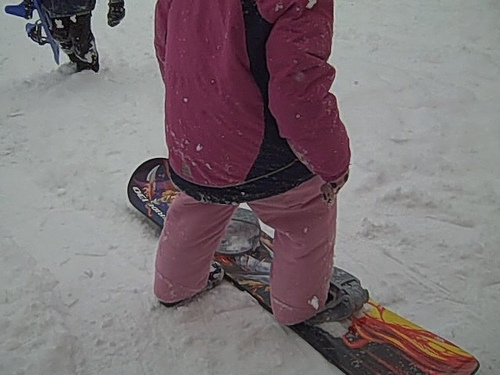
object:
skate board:
[126, 157, 480, 375]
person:
[1, 0, 126, 73]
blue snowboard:
[4, 0, 60, 65]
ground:
[418, 91, 450, 121]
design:
[339, 300, 473, 372]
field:
[21, 8, 447, 282]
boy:
[153, 0, 351, 326]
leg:
[245, 176, 341, 327]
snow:
[1, 325, 498, 372]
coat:
[153, 0, 352, 205]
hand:
[320, 171, 350, 205]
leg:
[101, 0, 126, 23]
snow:
[70, 44, 96, 65]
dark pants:
[43, 7, 99, 68]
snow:
[363, 67, 480, 190]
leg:
[152, 172, 236, 306]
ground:
[19, 80, 116, 180]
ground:
[7, 315, 140, 367]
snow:
[9, 113, 86, 317]